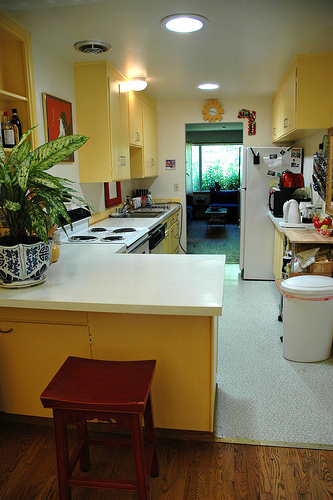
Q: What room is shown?
A: It is a kitchen.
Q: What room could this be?
A: It is a kitchen.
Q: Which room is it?
A: It is a kitchen.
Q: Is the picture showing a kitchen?
A: Yes, it is showing a kitchen.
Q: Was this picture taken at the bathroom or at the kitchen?
A: It was taken at the kitchen.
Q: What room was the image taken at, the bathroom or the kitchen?
A: It was taken at the kitchen.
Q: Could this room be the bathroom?
A: No, it is the kitchen.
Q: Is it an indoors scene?
A: Yes, it is indoors.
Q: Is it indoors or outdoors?
A: It is indoors.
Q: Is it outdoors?
A: No, it is indoors.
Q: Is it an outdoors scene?
A: No, it is indoors.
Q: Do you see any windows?
A: Yes, there is a window.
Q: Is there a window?
A: Yes, there is a window.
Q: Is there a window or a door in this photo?
A: Yes, there is a window.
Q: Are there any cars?
A: No, there are no cars.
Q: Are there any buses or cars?
A: No, there are no cars or buses.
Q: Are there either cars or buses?
A: No, there are no cars or buses.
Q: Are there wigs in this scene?
A: No, there are no wigs.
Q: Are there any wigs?
A: No, there are no wigs.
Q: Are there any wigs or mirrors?
A: No, there are no wigs or mirrors.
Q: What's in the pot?
A: The plant is in the pot.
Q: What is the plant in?
A: The plant is in the pot.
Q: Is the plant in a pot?
A: Yes, the plant is in a pot.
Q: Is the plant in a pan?
A: No, the plant is in a pot.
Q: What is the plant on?
A: The plant is on the counter.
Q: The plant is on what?
A: The plant is on the counter.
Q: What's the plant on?
A: The plant is on the counter.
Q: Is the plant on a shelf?
A: No, the plant is on the counter.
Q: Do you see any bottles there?
A: Yes, there is a bottle.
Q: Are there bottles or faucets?
A: Yes, there is a bottle.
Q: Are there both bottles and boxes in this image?
A: No, there is a bottle but no boxes.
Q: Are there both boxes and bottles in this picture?
A: No, there is a bottle but no boxes.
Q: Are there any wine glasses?
A: No, there are no wine glasses.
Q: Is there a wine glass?
A: No, there are no wine glasses.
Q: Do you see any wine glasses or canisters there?
A: No, there are no wine glasses or canisters.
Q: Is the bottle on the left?
A: Yes, the bottle is on the left of the image.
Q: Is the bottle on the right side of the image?
A: No, the bottle is on the left of the image.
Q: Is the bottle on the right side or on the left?
A: The bottle is on the left of the image.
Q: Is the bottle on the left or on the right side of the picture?
A: The bottle is on the left of the image.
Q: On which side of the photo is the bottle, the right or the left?
A: The bottle is on the left of the image.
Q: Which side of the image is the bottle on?
A: The bottle is on the left of the image.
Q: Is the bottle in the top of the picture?
A: Yes, the bottle is in the top of the image.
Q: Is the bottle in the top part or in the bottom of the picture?
A: The bottle is in the top of the image.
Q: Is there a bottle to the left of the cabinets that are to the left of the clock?
A: Yes, there is a bottle to the left of the cabinets.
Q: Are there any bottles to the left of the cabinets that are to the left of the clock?
A: Yes, there is a bottle to the left of the cabinets.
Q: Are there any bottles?
A: Yes, there is a bottle.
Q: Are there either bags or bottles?
A: Yes, there is a bottle.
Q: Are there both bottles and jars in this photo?
A: No, there is a bottle but no jars.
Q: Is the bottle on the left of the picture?
A: Yes, the bottle is on the left of the image.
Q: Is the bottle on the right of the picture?
A: No, the bottle is on the left of the image.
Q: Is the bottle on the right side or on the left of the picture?
A: The bottle is on the left of the image.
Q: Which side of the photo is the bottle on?
A: The bottle is on the left of the image.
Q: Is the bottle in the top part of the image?
A: Yes, the bottle is in the top of the image.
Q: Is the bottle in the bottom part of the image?
A: No, the bottle is in the top of the image.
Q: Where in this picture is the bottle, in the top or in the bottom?
A: The bottle is in the top of the image.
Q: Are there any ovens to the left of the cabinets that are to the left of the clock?
A: No, there is a bottle to the left of the cabinets.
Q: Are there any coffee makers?
A: Yes, there is a coffee maker.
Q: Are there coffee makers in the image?
A: Yes, there is a coffee maker.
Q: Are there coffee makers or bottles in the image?
A: Yes, there is a coffee maker.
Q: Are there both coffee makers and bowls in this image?
A: Yes, there are both a coffee maker and a bowl.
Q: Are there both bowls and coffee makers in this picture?
A: Yes, there are both a coffee maker and a bowl.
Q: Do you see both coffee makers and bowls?
A: Yes, there are both a coffee maker and a bowl.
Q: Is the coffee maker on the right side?
A: Yes, the coffee maker is on the right of the image.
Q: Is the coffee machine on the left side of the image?
A: No, the coffee machine is on the right of the image.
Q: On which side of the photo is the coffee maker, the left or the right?
A: The coffee maker is on the right of the image.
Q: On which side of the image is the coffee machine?
A: The coffee machine is on the right of the image.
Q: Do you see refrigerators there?
A: Yes, there is a refrigerator.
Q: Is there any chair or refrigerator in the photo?
A: Yes, there is a refrigerator.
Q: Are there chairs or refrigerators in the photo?
A: Yes, there is a refrigerator.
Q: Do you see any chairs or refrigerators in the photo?
A: Yes, there is a refrigerator.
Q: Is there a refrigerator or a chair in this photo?
A: Yes, there is a refrigerator.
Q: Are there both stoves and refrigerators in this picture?
A: Yes, there are both a refrigerator and a stove.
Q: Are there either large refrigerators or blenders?
A: Yes, there is a large refrigerator.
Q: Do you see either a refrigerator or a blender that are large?
A: Yes, the refrigerator is large.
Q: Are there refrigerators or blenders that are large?
A: Yes, the refrigerator is large.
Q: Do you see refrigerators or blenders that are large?
A: Yes, the refrigerator is large.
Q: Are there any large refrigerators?
A: Yes, there is a large refrigerator.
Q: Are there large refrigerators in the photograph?
A: Yes, there is a large refrigerator.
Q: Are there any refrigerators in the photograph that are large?
A: Yes, there is a refrigerator that is large.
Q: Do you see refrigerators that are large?
A: Yes, there is a refrigerator that is large.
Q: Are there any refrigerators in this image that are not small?
A: Yes, there is a large refrigerator.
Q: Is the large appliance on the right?
A: Yes, the refrigerator is on the right of the image.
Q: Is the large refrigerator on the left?
A: No, the refrigerator is on the right of the image.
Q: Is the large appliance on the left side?
A: No, the refrigerator is on the right of the image.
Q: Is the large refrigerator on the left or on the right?
A: The freezer is on the right of the image.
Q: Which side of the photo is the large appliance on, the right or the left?
A: The freezer is on the right of the image.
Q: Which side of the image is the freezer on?
A: The freezer is on the right of the image.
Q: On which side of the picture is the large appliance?
A: The freezer is on the right of the image.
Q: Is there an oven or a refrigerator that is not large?
A: No, there is a refrigerator but it is large.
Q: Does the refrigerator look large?
A: Yes, the refrigerator is large.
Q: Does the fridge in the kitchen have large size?
A: Yes, the refrigerator is large.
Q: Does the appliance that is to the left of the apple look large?
A: Yes, the refrigerator is large.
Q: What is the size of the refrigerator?
A: The refrigerator is large.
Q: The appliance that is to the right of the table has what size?
A: The refrigerator is large.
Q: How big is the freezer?
A: The freezer is large.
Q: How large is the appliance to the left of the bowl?
A: The freezer is large.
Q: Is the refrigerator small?
A: No, the refrigerator is large.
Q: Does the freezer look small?
A: No, the freezer is large.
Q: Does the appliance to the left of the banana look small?
A: No, the freezer is large.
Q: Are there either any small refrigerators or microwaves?
A: No, there is a refrigerator but it is large.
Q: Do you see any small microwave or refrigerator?
A: No, there is a refrigerator but it is large.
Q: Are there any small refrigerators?
A: No, there is a refrigerator but it is large.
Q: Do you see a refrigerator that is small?
A: No, there is a refrigerator but it is large.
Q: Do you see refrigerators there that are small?
A: No, there is a refrigerator but it is large.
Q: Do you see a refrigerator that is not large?
A: No, there is a refrigerator but it is large.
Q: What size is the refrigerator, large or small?
A: The refrigerator is large.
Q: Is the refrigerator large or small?
A: The refrigerator is large.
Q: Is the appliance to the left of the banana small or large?
A: The refrigerator is large.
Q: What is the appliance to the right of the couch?
A: The appliance is a refrigerator.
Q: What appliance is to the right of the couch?
A: The appliance is a refrigerator.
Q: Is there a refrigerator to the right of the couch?
A: Yes, there is a refrigerator to the right of the couch.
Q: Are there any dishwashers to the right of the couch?
A: No, there is a refrigerator to the right of the couch.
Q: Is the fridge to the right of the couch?
A: Yes, the fridge is to the right of the couch.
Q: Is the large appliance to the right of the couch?
A: Yes, the fridge is to the right of the couch.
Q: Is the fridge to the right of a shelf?
A: No, the fridge is to the right of the couch.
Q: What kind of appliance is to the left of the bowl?
A: The appliance is a refrigerator.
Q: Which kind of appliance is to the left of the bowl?
A: The appliance is a refrigerator.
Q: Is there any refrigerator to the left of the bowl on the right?
A: Yes, there is a refrigerator to the left of the bowl.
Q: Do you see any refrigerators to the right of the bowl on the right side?
A: No, the refrigerator is to the left of the bowl.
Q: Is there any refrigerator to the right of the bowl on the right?
A: No, the refrigerator is to the left of the bowl.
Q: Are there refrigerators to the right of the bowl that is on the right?
A: No, the refrigerator is to the left of the bowl.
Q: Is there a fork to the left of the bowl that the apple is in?
A: No, there is a refrigerator to the left of the bowl.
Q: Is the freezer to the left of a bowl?
A: Yes, the freezer is to the left of a bowl.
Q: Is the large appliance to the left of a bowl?
A: Yes, the freezer is to the left of a bowl.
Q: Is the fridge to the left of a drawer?
A: No, the fridge is to the left of a bowl.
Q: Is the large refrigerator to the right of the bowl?
A: No, the refrigerator is to the left of the bowl.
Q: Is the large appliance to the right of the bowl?
A: No, the refrigerator is to the left of the bowl.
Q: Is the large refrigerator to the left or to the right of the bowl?
A: The refrigerator is to the left of the bowl.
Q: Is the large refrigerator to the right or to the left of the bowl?
A: The refrigerator is to the left of the bowl.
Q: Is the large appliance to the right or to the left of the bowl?
A: The refrigerator is to the left of the bowl.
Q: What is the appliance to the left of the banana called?
A: The appliance is a refrigerator.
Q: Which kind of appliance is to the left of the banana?
A: The appliance is a refrigerator.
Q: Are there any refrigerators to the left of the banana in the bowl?
A: Yes, there is a refrigerator to the left of the banana.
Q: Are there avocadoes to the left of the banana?
A: No, there is a refrigerator to the left of the banana.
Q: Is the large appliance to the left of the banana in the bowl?
A: Yes, the refrigerator is to the left of the banana.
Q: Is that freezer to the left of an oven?
A: No, the freezer is to the left of the banana.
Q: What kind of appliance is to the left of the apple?
A: The appliance is a refrigerator.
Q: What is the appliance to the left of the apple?
A: The appliance is a refrigerator.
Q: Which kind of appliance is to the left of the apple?
A: The appliance is a refrigerator.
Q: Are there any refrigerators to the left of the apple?
A: Yes, there is a refrigerator to the left of the apple.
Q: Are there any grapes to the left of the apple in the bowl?
A: No, there is a refrigerator to the left of the apple.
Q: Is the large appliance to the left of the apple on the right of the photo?
A: Yes, the freezer is to the left of the apple.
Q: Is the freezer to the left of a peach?
A: No, the freezer is to the left of the apple.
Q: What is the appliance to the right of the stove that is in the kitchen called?
A: The appliance is a refrigerator.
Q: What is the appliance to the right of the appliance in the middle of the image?
A: The appliance is a refrigerator.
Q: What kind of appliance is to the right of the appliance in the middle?
A: The appliance is a refrigerator.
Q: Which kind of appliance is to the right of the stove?
A: The appliance is a refrigerator.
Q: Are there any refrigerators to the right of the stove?
A: Yes, there is a refrigerator to the right of the stove.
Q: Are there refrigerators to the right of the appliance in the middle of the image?
A: Yes, there is a refrigerator to the right of the stove.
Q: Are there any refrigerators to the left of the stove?
A: No, the refrigerator is to the right of the stove.